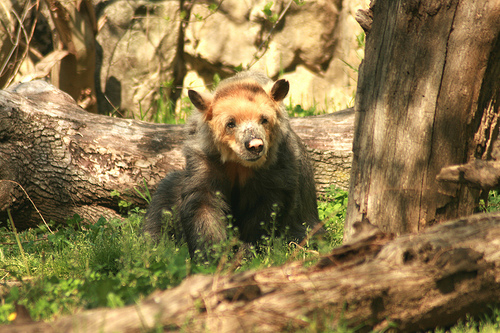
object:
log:
[3, 85, 363, 226]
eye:
[226, 119, 237, 129]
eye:
[260, 117, 270, 125]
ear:
[184, 87, 210, 112]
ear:
[269, 78, 291, 100]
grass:
[4, 190, 347, 315]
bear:
[138, 68, 329, 267]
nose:
[238, 129, 265, 156]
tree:
[339, 0, 495, 248]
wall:
[97, 0, 354, 125]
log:
[0, 211, 495, 332]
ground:
[53, 91, 450, 321]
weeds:
[97, 190, 221, 278]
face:
[203, 81, 278, 168]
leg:
[173, 163, 238, 246]